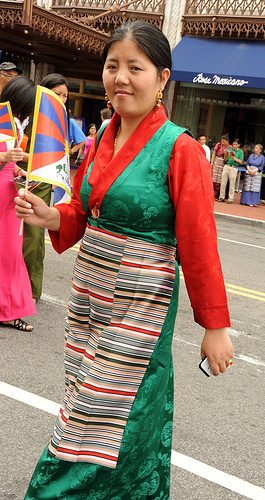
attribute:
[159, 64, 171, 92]
left ear — woman's 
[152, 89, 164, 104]
earring — long, yellow, red, blue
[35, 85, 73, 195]
flag — yellow, red, white, blue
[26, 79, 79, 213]
flag — blue, red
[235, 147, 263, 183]
dress — purple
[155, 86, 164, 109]
ear rings — yellow and red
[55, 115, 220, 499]
dress — red, green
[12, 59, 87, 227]
flag — wooden stick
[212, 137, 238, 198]
pants — khaki, light colored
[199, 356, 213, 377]
phone — white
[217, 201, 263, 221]
sidewalk — orange, brick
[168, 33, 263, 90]
awning — blue, white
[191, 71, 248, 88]
lettering — white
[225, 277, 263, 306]
line — double, yellow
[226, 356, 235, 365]
ring — gold, red stone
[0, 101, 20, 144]
flag — red and blue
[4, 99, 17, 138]
boarder — yellow 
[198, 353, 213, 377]
cellphone — white, black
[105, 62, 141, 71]
eyes — womans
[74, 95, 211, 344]
shirt — button down, green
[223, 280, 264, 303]
yellow lines — yellow painted 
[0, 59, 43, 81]
cap — gray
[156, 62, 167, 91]
ear — woman's right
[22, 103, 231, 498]
dress — printed, red and green, colorful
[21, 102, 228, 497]
robe — beautiful, green, red